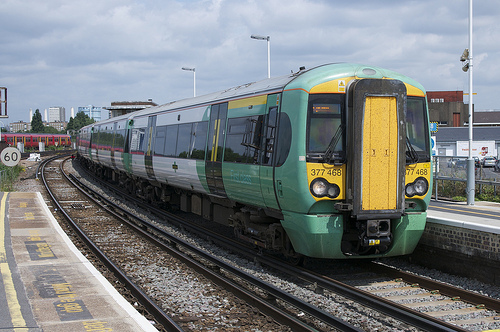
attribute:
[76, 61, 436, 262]
train — green, yellow, multicolored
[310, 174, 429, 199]
headlights — off, white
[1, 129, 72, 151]
train — red, long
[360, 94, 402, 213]
door — yellow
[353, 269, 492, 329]
gravel — gray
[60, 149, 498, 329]
tracks — brown, black, gray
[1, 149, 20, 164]
number — 60 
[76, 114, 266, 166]
windows — dark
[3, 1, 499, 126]
sky — overcast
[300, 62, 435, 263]
train front — yellow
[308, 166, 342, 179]
numbers — black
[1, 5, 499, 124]
clouds — white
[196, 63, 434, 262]
engie — green, yellow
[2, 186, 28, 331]
line — yellow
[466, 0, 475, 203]
pole — tall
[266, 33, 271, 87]
pole — tall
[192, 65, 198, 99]
pole — tall